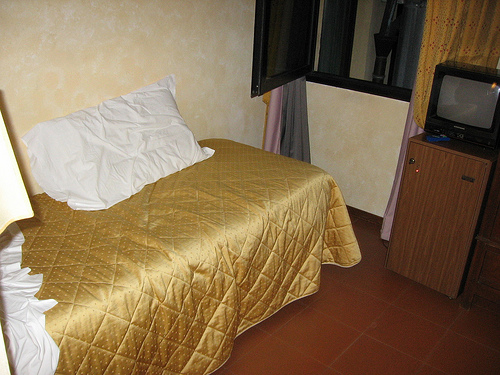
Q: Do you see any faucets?
A: No, there are no faucets.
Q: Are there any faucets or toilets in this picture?
A: No, there are no faucets or toilets.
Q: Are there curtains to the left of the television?
A: Yes, there is a curtain to the left of the television.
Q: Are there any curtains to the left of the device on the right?
A: Yes, there is a curtain to the left of the television.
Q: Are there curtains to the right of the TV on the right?
A: No, the curtain is to the left of the television.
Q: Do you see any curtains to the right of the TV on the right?
A: No, the curtain is to the left of the television.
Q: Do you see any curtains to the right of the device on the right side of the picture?
A: No, the curtain is to the left of the television.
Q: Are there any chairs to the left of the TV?
A: No, there is a curtain to the left of the TV.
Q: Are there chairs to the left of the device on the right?
A: No, there is a curtain to the left of the TV.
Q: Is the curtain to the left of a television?
A: Yes, the curtain is to the left of a television.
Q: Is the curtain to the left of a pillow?
A: No, the curtain is to the left of a television.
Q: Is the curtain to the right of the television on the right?
A: No, the curtain is to the left of the TV.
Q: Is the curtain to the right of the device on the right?
A: No, the curtain is to the left of the TV.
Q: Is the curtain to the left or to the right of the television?
A: The curtain is to the left of the television.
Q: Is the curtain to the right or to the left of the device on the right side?
A: The curtain is to the left of the television.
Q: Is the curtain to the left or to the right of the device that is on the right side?
A: The curtain is to the left of the television.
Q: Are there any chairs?
A: No, there are no chairs.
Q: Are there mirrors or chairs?
A: No, there are no chairs or mirrors.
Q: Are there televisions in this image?
A: Yes, there is a television.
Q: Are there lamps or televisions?
A: Yes, there is a television.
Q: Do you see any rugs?
A: No, there are no rugs.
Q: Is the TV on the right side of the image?
A: Yes, the TV is on the right of the image.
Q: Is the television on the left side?
A: No, the television is on the right of the image.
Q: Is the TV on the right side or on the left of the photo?
A: The TV is on the right of the image.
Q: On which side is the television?
A: The television is on the right of the image.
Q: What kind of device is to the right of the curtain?
A: The device is a television.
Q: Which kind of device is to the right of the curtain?
A: The device is a television.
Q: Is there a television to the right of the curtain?
A: Yes, there is a television to the right of the curtain.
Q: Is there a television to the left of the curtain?
A: No, the television is to the right of the curtain.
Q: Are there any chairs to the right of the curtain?
A: No, there is a television to the right of the curtain.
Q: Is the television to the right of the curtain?
A: Yes, the television is to the right of the curtain.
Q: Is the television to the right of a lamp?
A: No, the television is to the right of the curtain.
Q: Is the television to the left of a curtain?
A: No, the television is to the right of a curtain.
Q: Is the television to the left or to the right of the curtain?
A: The television is to the right of the curtain.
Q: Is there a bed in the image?
A: Yes, there is a bed.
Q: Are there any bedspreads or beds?
A: Yes, there is a bed.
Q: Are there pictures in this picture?
A: No, there are no pictures.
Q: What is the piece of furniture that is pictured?
A: The piece of furniture is a bed.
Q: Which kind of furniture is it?
A: The piece of furniture is a bed.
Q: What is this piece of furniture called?
A: This is a bed.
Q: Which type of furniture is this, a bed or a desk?
A: This is a bed.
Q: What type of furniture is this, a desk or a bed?
A: This is a bed.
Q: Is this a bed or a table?
A: This is a bed.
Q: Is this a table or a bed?
A: This is a bed.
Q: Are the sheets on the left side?
A: Yes, the sheets are on the left of the image.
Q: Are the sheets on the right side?
A: No, the sheets are on the left of the image.